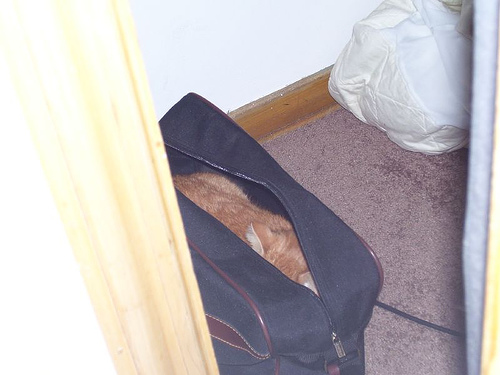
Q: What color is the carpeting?
A: Pink.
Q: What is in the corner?
A: A garbage bag.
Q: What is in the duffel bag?
A: A cat.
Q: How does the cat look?
A: Sleepy.